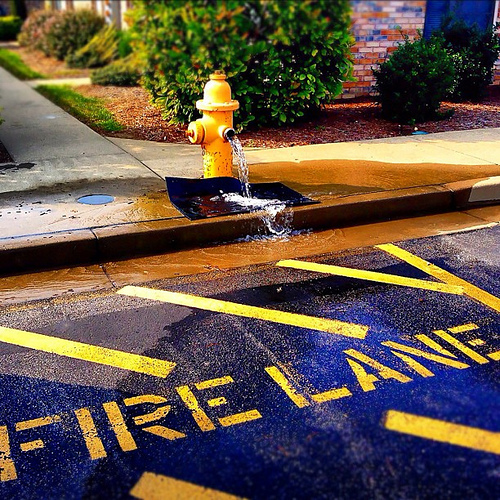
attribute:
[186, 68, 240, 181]
fire hydrant — yellow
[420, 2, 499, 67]
door — black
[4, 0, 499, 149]
building — side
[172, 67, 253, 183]
hydrant — small, yellow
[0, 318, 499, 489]
words — yellow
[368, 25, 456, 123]
bush — green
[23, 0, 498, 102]
building — brick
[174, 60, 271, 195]
hydrant — yellow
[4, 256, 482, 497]
road — wet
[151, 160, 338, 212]
matt — black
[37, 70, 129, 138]
grass — Green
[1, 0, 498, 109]
building — brick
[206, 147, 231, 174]
paint — yellow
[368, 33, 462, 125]
bush — green 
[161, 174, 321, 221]
mat — blue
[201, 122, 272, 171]
water — flowing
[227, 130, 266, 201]
water stream — streaming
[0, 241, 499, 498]
lines — Yellow 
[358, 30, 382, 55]
bricks — different colors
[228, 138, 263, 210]
water — cold, gushing, yellow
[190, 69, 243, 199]
fire hydrant — official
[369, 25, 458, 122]
dark-green bush — green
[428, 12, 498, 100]
dark-green bush — green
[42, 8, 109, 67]
dark-green bush — green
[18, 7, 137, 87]
bushes — small 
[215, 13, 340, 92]
leaves — green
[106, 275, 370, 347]
line — diagonal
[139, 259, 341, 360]
line — yellow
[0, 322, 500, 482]
writing — yellow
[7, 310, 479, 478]
fire lane — designated, paved, black and yellow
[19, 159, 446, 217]
sidewalk — cement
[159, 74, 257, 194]
hydrant — fire, yellow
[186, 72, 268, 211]
hydrant — fire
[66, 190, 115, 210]
hole — metal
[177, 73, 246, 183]
hydrant — fire, yellow